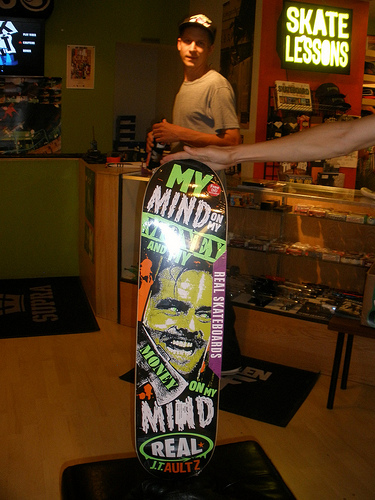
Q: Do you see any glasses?
A: No, there are no glasses.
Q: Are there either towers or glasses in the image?
A: No, there are no glasses or towers.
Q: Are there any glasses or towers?
A: No, there are no glasses or towers.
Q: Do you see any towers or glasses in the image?
A: No, there are no glasses or towers.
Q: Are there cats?
A: No, there are no cats.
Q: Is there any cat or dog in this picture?
A: No, there are no cats or dogs.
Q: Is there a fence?
A: No, there are no fences.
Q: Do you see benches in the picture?
A: Yes, there is a bench.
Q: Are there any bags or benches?
A: Yes, there is a bench.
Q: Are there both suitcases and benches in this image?
A: No, there is a bench but no suitcases.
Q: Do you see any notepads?
A: No, there are no notepads.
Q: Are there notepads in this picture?
A: No, there are no notepads.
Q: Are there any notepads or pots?
A: No, there are no notepads or pots.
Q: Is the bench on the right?
A: Yes, the bench is on the right of the image.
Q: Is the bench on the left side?
A: No, the bench is on the right of the image.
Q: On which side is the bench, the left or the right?
A: The bench is on the right of the image.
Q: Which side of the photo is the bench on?
A: The bench is on the right of the image.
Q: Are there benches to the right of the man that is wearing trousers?
A: Yes, there is a bench to the right of the man.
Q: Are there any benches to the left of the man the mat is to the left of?
A: No, the bench is to the right of the man.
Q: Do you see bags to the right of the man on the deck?
A: No, there is a bench to the right of the man.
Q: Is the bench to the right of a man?
A: Yes, the bench is to the right of a man.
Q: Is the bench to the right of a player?
A: No, the bench is to the right of a man.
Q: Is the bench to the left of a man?
A: No, the bench is to the right of a man.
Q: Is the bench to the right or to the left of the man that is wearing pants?
A: The bench is to the right of the man.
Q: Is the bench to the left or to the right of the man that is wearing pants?
A: The bench is to the right of the man.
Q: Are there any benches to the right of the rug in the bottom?
A: Yes, there is a bench to the right of the rug.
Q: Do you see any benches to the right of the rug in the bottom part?
A: Yes, there is a bench to the right of the rug.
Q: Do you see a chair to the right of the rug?
A: No, there is a bench to the right of the rug.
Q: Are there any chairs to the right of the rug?
A: No, there is a bench to the right of the rug.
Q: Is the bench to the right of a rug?
A: Yes, the bench is to the right of a rug.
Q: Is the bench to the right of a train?
A: No, the bench is to the right of a rug.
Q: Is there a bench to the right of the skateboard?
A: Yes, there is a bench to the right of the skateboard.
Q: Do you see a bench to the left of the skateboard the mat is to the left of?
A: No, the bench is to the right of the skateboard.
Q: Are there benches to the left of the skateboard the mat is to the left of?
A: No, the bench is to the right of the skateboard.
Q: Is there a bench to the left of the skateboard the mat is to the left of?
A: No, the bench is to the right of the skateboard.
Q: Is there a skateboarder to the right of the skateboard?
A: No, there is a bench to the right of the skateboard.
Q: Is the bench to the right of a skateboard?
A: Yes, the bench is to the right of a skateboard.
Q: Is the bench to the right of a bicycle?
A: No, the bench is to the right of a skateboard.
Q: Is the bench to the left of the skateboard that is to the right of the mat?
A: No, the bench is to the right of the skateboard.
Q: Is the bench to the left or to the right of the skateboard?
A: The bench is to the right of the skateboard.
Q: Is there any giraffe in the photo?
A: No, there are no giraffes.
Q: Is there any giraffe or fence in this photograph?
A: No, there are no giraffes or fences.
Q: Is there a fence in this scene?
A: No, there are no fences.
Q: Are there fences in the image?
A: No, there are no fences.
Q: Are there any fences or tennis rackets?
A: No, there are no fences or tennis rackets.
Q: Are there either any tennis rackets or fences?
A: No, there are no fences or tennis rackets.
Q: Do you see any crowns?
A: Yes, there is a crown.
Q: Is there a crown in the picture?
A: Yes, there is a crown.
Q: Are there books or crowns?
A: Yes, there is a crown.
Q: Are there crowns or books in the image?
A: Yes, there is a crown.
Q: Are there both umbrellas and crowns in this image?
A: No, there is a crown but no umbrellas.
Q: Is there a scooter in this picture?
A: No, there are no scooters.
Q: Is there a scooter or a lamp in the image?
A: No, there are no scooters or lamps.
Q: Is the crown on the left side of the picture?
A: Yes, the crown is on the left of the image.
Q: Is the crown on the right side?
A: No, the crown is on the left of the image.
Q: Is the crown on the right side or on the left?
A: The crown is on the left of the image.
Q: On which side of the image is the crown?
A: The crown is on the left of the image.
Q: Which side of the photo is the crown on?
A: The crown is on the left of the image.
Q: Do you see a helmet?
A: No, there are no helmets.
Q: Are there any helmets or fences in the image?
A: No, there are no helmets or fences.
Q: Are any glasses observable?
A: No, there are no glasses.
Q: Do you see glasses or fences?
A: No, there are no glasses or fences.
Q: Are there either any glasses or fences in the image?
A: No, there are no glasses or fences.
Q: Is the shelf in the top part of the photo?
A: Yes, the shelf is in the top of the image.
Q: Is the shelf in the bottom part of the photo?
A: No, the shelf is in the top of the image.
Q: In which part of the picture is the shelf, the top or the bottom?
A: The shelf is in the top of the image.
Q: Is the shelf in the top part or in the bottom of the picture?
A: The shelf is in the top of the image.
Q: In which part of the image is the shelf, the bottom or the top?
A: The shelf is in the top of the image.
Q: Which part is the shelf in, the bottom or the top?
A: The shelf is in the top of the image.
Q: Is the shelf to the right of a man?
A: No, the shelf is to the left of a man.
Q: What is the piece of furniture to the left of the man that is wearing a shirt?
A: The piece of furniture is a shelf.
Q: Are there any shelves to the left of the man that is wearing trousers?
A: Yes, there is a shelf to the left of the man.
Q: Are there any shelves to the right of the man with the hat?
A: No, the shelf is to the left of the man.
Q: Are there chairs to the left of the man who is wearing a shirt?
A: No, there is a shelf to the left of the man.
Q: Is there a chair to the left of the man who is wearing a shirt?
A: No, there is a shelf to the left of the man.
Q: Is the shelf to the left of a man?
A: Yes, the shelf is to the left of a man.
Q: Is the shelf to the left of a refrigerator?
A: No, the shelf is to the left of a man.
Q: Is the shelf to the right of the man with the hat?
A: No, the shelf is to the left of the man.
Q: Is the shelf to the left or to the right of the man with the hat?
A: The shelf is to the left of the man.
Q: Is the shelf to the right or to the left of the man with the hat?
A: The shelf is to the left of the man.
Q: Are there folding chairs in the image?
A: No, there are no folding chairs.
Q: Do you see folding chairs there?
A: No, there are no folding chairs.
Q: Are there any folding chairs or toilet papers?
A: No, there are no folding chairs or toilet papers.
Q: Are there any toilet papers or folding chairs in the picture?
A: No, there are no folding chairs or toilet papers.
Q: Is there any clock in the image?
A: No, there are no clocks.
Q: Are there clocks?
A: No, there are no clocks.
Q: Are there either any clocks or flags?
A: No, there are no clocks or flags.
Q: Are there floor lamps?
A: No, there are no floor lamps.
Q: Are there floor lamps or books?
A: No, there are no floor lamps or books.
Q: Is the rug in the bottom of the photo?
A: Yes, the rug is in the bottom of the image.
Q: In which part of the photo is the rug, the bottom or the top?
A: The rug is in the bottom of the image.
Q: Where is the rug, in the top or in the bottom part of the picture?
A: The rug is in the bottom of the image.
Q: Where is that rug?
A: The rug is on the floor.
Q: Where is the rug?
A: The rug is on the floor.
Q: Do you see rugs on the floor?
A: Yes, there is a rug on the floor.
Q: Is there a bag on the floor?
A: No, there is a rug on the floor.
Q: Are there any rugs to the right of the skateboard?
A: Yes, there is a rug to the right of the skateboard.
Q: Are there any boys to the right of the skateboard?
A: No, there is a rug to the right of the skateboard.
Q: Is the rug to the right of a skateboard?
A: Yes, the rug is to the right of a skateboard.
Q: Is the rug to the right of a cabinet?
A: No, the rug is to the right of a skateboard.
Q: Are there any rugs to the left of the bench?
A: Yes, there is a rug to the left of the bench.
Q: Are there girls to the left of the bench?
A: No, there is a rug to the left of the bench.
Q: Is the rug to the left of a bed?
A: No, the rug is to the left of the bench.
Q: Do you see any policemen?
A: No, there are no policemen.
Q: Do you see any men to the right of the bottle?
A: Yes, there is a man to the right of the bottle.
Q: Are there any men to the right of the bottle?
A: Yes, there is a man to the right of the bottle.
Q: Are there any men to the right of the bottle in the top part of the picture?
A: Yes, there is a man to the right of the bottle.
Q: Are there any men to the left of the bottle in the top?
A: No, the man is to the right of the bottle.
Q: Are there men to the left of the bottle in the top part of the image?
A: No, the man is to the right of the bottle.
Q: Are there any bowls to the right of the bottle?
A: No, there is a man to the right of the bottle.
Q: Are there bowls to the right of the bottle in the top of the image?
A: No, there is a man to the right of the bottle.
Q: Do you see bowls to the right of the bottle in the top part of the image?
A: No, there is a man to the right of the bottle.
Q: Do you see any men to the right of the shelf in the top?
A: Yes, there is a man to the right of the shelf.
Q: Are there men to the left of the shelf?
A: No, the man is to the right of the shelf.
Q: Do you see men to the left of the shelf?
A: No, the man is to the right of the shelf.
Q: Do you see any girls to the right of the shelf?
A: No, there is a man to the right of the shelf.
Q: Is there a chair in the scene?
A: No, there are no chairs.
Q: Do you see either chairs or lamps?
A: No, there are no chairs or lamps.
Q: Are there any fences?
A: No, there are no fences.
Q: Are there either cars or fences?
A: No, there are no fences or cars.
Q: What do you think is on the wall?
A: The sign is on the wall.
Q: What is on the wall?
A: The sign is on the wall.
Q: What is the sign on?
A: The sign is on the wall.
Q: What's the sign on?
A: The sign is on the wall.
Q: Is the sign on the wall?
A: Yes, the sign is on the wall.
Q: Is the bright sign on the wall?
A: Yes, the sign is on the wall.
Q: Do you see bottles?
A: Yes, there is a bottle.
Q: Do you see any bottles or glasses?
A: Yes, there is a bottle.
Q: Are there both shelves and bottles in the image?
A: Yes, there are both a bottle and a shelf.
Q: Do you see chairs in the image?
A: No, there are no chairs.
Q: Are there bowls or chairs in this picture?
A: No, there are no chairs or bowls.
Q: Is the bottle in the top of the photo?
A: Yes, the bottle is in the top of the image.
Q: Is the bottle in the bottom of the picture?
A: No, the bottle is in the top of the image.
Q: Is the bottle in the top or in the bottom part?
A: The bottle is in the top of the image.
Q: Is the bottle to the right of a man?
A: No, the bottle is to the left of a man.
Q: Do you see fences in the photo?
A: No, there are no fences.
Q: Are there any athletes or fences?
A: No, there are no fences or athletes.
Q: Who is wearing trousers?
A: The man is wearing trousers.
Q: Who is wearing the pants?
A: The man is wearing trousers.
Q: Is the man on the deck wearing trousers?
A: Yes, the man is wearing trousers.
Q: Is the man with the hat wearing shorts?
A: No, the man is wearing trousers.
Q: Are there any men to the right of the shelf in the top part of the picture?
A: Yes, there is a man to the right of the shelf.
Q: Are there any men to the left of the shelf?
A: No, the man is to the right of the shelf.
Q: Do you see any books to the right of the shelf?
A: No, there is a man to the right of the shelf.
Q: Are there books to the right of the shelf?
A: No, there is a man to the right of the shelf.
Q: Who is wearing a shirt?
A: The man is wearing a shirt.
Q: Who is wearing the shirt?
A: The man is wearing a shirt.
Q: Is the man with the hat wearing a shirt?
A: Yes, the man is wearing a shirt.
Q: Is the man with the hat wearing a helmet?
A: No, the man is wearing a shirt.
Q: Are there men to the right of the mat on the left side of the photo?
A: Yes, there is a man to the right of the mat.